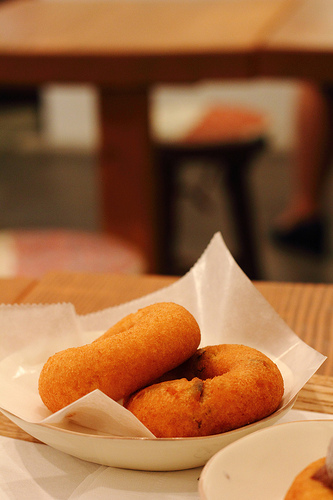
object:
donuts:
[122, 344, 285, 437]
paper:
[0, 230, 328, 438]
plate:
[0, 329, 300, 472]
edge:
[26, 422, 226, 442]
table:
[0, 270, 333, 500]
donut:
[38, 301, 201, 414]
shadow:
[13, 436, 208, 500]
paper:
[0, 409, 333, 500]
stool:
[148, 128, 270, 286]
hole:
[165, 360, 229, 382]